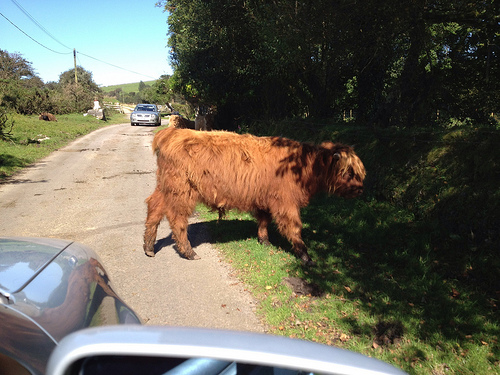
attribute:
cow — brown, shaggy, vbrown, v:
[141, 123, 367, 249]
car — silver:
[130, 93, 157, 135]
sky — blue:
[87, 8, 124, 53]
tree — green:
[386, 53, 442, 108]